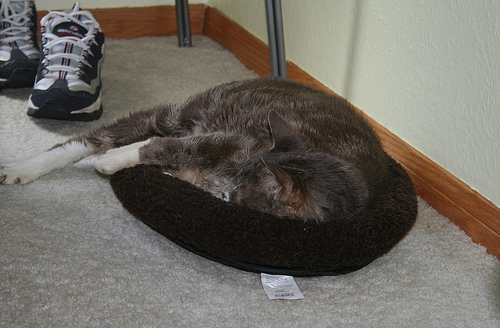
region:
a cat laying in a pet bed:
[33, 73, 385, 255]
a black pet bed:
[155, 160, 416, 275]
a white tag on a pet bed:
[238, 262, 308, 312]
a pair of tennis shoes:
[0, 13, 122, 109]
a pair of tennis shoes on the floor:
[0, 20, 115, 122]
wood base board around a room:
[120, 0, 214, 55]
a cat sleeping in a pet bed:
[170, 94, 349, 226]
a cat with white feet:
[0, 135, 157, 203]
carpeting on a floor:
[0, 265, 169, 321]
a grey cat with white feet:
[72, 83, 331, 216]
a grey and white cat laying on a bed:
[16, 68, 393, 239]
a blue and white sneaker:
[33, 2, 120, 129]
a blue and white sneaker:
[3, 3, 44, 90]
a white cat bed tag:
[257, 263, 307, 309]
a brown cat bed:
[107, 97, 436, 289]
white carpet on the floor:
[3, 10, 493, 322]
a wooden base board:
[198, 0, 493, 262]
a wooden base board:
[48, 3, 216, 59]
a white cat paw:
[0, 150, 86, 205]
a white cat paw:
[93, 141, 150, 172]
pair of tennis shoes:
[0, 2, 120, 122]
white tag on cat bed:
[248, 265, 315, 310]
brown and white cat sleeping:
[0, 68, 440, 268]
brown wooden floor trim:
[425, 169, 497, 239]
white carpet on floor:
[4, 239, 164, 326]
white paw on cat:
[94, 127, 149, 178]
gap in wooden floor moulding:
[189, 2, 224, 37]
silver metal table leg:
[247, 0, 288, 76]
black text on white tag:
[269, 287, 300, 298]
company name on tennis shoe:
[52, 19, 87, 40]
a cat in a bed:
[98, 63, 469, 323]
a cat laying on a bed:
[118, 29, 405, 311]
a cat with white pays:
[129, 58, 407, 293]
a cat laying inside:
[119, 29, 471, 324]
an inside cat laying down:
[105, 61, 392, 323]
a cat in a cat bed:
[169, 44, 396, 308]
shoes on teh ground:
[22, 14, 146, 192]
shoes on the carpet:
[21, 1, 156, 136]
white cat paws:
[49, 121, 190, 196]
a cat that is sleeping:
[144, 68, 395, 302]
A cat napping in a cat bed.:
[0, 76, 417, 275]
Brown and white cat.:
[4, 74, 384, 216]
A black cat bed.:
[109, 134, 419, 276]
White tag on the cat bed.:
[259, 273, 301, 303]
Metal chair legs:
[26, 0, 286, 80]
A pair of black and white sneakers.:
[0, 0, 106, 122]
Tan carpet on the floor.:
[0, 37, 499, 327]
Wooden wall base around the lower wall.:
[0, 5, 499, 255]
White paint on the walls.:
[29, 0, 499, 203]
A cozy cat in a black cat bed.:
[0, 73, 415, 276]